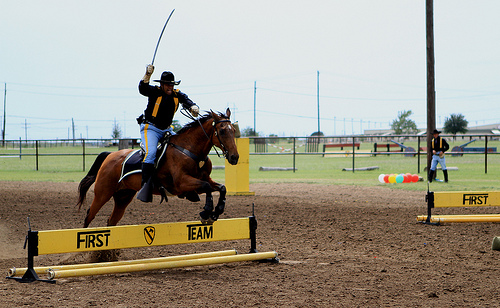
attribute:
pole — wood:
[35, 137, 39, 172]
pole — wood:
[19, 135, 100, 195]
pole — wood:
[424, 0, 443, 185]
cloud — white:
[138, 2, 458, 137]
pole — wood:
[249, 79, 261, 147]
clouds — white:
[7, 0, 497, 131]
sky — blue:
[0, 0, 497, 138]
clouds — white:
[257, 28, 422, 80]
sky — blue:
[1, 0, 498, 119]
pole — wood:
[420, 3, 452, 184]